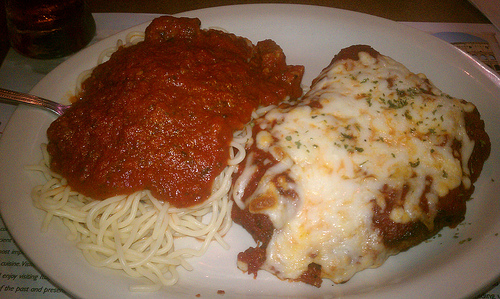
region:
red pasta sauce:
[47, 11, 305, 209]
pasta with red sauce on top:
[38, 19, 300, 280]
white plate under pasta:
[7, 1, 497, 298]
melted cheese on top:
[274, 49, 469, 279]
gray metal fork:
[4, 88, 74, 116]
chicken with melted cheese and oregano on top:
[234, 43, 498, 284]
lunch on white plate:
[30, 13, 487, 290]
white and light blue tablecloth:
[10, 19, 498, 297]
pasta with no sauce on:
[41, 193, 231, 275]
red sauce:
[48, 15, 303, 215]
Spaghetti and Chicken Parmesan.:
[1, 0, 498, 297]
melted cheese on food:
[286, 117, 378, 243]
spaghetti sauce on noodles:
[133, 101, 204, 171]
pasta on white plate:
[106, 214, 165, 261]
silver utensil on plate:
[5, 84, 56, 134]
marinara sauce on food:
[363, 198, 442, 243]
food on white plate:
[44, 95, 492, 282]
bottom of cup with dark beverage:
[15, 33, 98, 63]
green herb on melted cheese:
[340, 102, 411, 157]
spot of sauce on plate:
[185, 275, 236, 295]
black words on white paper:
[11, 263, 35, 287]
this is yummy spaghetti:
[53, 23, 306, 291]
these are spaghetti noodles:
[28, 125, 254, 282]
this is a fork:
[0, 82, 70, 125]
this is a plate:
[3, 2, 498, 297]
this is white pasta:
[30, 105, 240, 281]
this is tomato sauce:
[45, 15, 315, 211]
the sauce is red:
[46, 7, 304, 207]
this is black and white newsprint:
[1, 7, 496, 297]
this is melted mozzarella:
[216, 40, 481, 290]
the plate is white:
[0, 2, 496, 297]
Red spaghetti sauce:
[43, 16, 305, 197]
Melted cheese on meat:
[257, 55, 461, 274]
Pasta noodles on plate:
[32, 172, 238, 280]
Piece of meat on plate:
[224, 42, 484, 290]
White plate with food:
[1, 2, 498, 295]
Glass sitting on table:
[3, 2, 105, 66]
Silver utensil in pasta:
[0, 78, 82, 149]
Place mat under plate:
[2, 9, 498, 297]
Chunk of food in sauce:
[137, 14, 206, 50]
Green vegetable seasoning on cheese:
[307, 62, 438, 170]